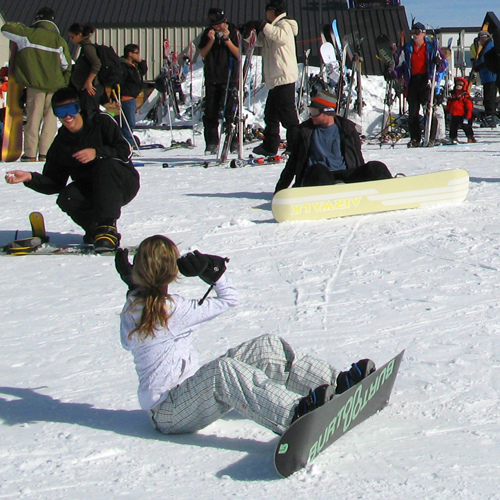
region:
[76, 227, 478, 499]
woman snowboarding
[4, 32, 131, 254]
Man wearing ski goggles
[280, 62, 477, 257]
man waiting to snowboard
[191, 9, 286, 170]
People getting ready to ski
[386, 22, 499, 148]
Parent and child getting ready to ski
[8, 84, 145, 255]
Man smiling at woman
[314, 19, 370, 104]
Collection of skis and snowboards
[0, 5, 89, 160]
Man in green jacket leaning on snow board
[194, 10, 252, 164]
Man putting on skiing gear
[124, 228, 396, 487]
Woman in white snowboarding outfit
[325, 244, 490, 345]
The ground is snow covered.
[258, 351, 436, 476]
Her board is grey.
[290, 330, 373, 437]
Her boots are black.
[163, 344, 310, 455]
Her pants are white.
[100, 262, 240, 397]
Her jacket is white.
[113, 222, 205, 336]
She has long hair.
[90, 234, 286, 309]
She is wearing black gloves.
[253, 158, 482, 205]
His board is yellow and white.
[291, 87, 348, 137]
He is wearing a hat.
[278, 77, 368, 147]
He is wearing goggles.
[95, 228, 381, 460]
woman sits on snow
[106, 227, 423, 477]
woman has on a snowboard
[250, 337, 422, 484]
snowboard is black with green letters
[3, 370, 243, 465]
shadow of woman cast on the snow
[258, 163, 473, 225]
snowboard is yellow and white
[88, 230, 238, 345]
blonde woman wears black gloves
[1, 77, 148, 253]
man wearing goggles is smiling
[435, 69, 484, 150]
a kid wearing a red snow coat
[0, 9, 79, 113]
man wears a green jacket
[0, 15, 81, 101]
jacket has a white strip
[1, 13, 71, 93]
olive green and white jacket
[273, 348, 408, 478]
black snowboard with Burton in green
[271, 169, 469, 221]
yellow and white snowboard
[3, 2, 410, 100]
building in the background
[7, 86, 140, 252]
person in black crouching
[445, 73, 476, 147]
baby in red coat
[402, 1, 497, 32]
section of blue sky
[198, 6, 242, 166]
man wearing black with arms up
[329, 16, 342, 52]
bright blue ski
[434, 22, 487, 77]
white building in background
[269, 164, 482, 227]
Really Light Yellow Snow board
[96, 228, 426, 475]
Female Snow Boarder on the Ground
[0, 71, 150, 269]
Male Snow Boarder Dressed in Black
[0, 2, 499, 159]
Groups of People in the Background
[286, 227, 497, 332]
White snow with various tracks in it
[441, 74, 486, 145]
Small Child in red Coat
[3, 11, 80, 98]
A Dark Green Coat with a white line across it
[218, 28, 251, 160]
A pair of Red and White Skis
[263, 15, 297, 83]
A nice Tan Coat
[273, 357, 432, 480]
A Dark Colored Snow Board